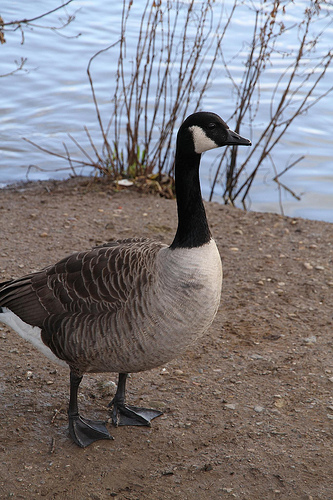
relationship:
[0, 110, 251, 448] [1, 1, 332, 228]
bird near water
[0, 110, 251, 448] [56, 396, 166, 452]
bird has feet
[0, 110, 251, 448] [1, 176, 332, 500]
bird above ground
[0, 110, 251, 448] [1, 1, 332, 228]
bird by water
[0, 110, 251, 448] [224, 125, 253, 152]
bird has beak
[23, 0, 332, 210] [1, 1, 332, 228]
vegetation by water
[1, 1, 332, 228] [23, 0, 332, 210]
water near vegetation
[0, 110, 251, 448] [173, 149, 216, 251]
bird has neck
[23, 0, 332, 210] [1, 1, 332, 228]
vegetation near water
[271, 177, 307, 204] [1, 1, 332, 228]
reflection on water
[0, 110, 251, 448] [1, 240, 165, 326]
bird has back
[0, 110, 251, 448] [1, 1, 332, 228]
bird beside water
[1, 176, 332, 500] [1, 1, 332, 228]
ground by water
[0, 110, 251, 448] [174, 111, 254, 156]
bird has head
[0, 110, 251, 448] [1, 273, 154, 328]
bird has wing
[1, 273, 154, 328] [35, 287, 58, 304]
wing has feather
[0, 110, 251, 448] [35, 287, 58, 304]
bird has feather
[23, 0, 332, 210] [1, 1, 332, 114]
vegetation by water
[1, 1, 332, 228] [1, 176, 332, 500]
water by ground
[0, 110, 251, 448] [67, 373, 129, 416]
bird has legs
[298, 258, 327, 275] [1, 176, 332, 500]
rocks above ground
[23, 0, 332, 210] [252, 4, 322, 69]
vegetation has leaves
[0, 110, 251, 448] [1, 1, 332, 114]
bird standing by water